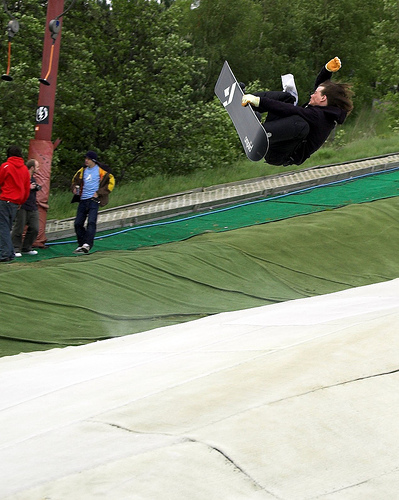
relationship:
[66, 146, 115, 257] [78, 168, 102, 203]
man wearing shirt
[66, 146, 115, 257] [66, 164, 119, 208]
man wearing jacket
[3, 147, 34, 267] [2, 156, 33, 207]
man wearing jacket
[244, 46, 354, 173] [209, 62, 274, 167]
man grabbing snowboard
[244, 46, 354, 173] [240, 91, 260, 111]
man wearing glove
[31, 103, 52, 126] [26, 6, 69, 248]
sticker on pole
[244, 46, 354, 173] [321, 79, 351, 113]
man has hair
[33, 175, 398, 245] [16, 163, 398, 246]
hose on mats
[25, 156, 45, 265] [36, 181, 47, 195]
man holding camera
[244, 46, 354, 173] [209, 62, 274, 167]
man on snowboard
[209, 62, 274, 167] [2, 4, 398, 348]
snowboard in air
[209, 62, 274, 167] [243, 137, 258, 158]
snowboard has letters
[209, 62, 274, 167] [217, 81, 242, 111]
snowboard has design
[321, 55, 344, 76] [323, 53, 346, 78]
glove on hand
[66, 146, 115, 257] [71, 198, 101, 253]
man wearing jeans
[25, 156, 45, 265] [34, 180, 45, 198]
man holding soda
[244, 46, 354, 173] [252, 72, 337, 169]
man wearing black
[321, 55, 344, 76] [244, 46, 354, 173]
glove on man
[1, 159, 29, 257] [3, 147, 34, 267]
back of man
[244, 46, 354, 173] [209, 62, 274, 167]
man holding snowboard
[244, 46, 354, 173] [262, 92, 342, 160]
man wearing shirt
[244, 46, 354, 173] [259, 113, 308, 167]
man wearing pants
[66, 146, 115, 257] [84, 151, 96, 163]
man wearing hat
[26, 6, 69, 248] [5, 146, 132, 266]
pole near people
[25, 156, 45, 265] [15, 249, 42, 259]
man wearing shoes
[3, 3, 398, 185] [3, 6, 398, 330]
trees in background